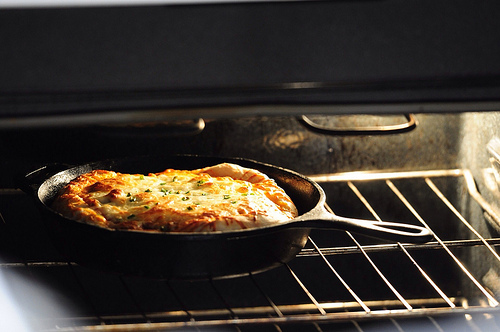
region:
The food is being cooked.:
[14, 136, 459, 287]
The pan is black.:
[13, 131, 435, 273]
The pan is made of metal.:
[23, 134, 437, 282]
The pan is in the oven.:
[3, 97, 498, 327]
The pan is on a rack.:
[8, 150, 497, 329]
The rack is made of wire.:
[263, 167, 495, 324]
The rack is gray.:
[266, 162, 498, 328]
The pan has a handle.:
[285, 195, 451, 260]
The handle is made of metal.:
[288, 189, 448, 251]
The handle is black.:
[279, 187, 446, 258]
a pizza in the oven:
[25, 112, 488, 287]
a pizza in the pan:
[50, 160, 297, 233]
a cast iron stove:
[17, 159, 432, 286]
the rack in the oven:
[433, 156, 485, 329]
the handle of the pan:
[325, 204, 437, 257]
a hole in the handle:
[374, 222, 423, 237]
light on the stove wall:
[422, 112, 488, 152]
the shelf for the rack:
[479, 212, 499, 294]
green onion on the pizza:
[112, 174, 242, 218]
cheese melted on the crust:
[172, 209, 249, 234]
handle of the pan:
[327, 215, 471, 255]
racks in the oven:
[332, 180, 440, 309]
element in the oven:
[299, 101, 427, 154]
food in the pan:
[4, 120, 436, 318]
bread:
[235, 188, 294, 243]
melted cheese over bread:
[192, 202, 257, 237]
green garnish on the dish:
[108, 157, 223, 213]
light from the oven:
[444, 99, 497, 173]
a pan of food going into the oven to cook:
[33, 41, 445, 321]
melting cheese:
[79, 138, 248, 240]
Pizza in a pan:
[8, 120, 480, 297]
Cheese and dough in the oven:
[23, 144, 362, 266]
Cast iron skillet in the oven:
[15, 148, 460, 284]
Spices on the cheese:
[78, 151, 263, 224]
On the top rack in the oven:
[7, 145, 474, 328]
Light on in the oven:
[145, 117, 496, 229]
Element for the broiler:
[277, 112, 465, 162]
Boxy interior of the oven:
[7, 106, 483, 327]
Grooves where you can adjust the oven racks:
[432, 122, 497, 302]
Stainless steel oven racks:
[318, 157, 492, 327]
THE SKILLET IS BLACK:
[3, 142, 438, 281]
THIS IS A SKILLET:
[19, 150, 444, 284]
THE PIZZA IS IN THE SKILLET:
[16, 147, 448, 298]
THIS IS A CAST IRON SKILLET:
[19, 156, 439, 288]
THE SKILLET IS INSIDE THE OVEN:
[22, 143, 442, 292]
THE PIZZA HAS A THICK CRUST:
[26, 146, 301, 256]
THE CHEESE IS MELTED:
[66, 168, 276, 244]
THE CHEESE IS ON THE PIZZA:
[70, 167, 274, 233]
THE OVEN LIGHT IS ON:
[293, 83, 499, 210]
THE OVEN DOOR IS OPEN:
[0, 1, 496, 329]